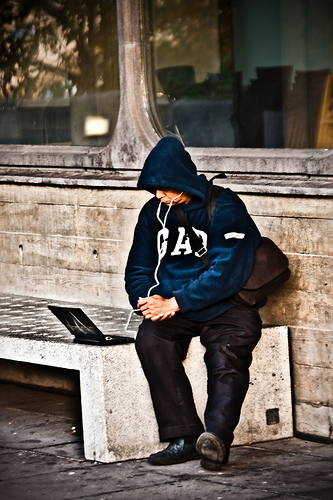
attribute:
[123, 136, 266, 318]
hoodie — blue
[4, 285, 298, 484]
bench — park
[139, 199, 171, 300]
headphone — white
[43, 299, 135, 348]
laptop — black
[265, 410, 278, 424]
hole — rectangular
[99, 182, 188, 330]
earphones — plugged in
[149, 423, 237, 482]
shoes — black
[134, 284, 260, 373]
pants — black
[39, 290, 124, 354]
laptop — open, black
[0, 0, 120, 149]
window — large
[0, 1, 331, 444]
building — large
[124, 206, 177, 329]
cable — white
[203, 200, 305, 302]
satchel — brow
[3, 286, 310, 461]
bench — concrete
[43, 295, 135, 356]
laptop — black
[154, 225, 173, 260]
letter — white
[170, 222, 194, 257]
letter — white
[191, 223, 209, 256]
letter — white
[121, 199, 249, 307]
sleeves — long